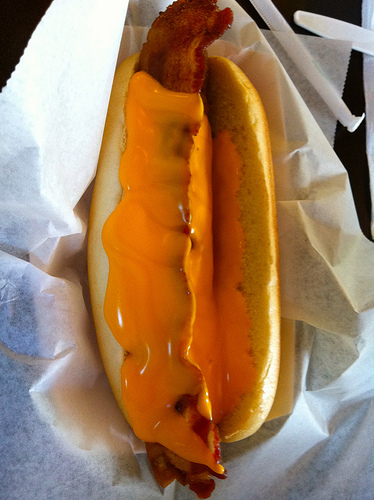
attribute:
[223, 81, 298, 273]
bun — open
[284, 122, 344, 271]
crinkled — white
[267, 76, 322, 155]
paper — white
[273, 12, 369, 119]
corner — white, under